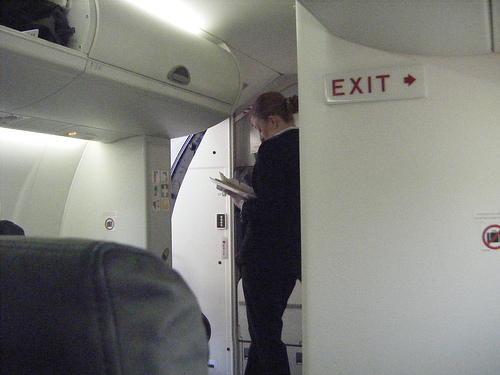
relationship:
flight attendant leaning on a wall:
[213, 74, 345, 188] [270, 79, 388, 371]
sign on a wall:
[311, 65, 441, 119] [305, 22, 485, 311]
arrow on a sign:
[396, 66, 423, 95] [322, 57, 432, 117]